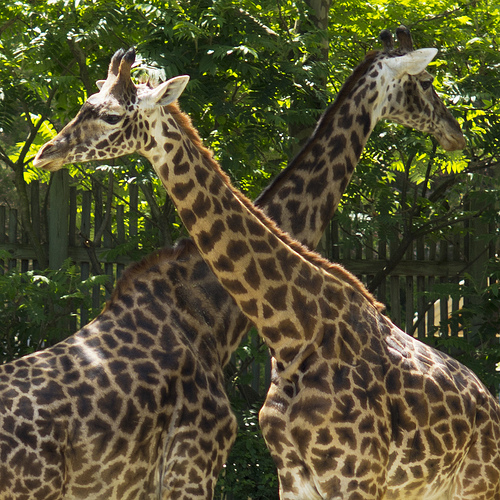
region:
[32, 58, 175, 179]
head of the photo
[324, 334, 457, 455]
brown spots on the animal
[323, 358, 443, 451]
white lines on the giraffe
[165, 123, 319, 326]
neck of the giraffe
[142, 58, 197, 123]
ear of the giraffe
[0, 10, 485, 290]
two different giraffes in the photo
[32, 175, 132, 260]
fence behind the giraffes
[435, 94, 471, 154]
nose of the giraffe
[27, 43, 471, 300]
giraffes facing different directions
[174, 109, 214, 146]
hair on the back of the giraffe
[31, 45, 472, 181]
Two giraffes in front of trees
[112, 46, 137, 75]
Protrusions on giraffe on the left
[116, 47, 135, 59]
Black hairs sticking out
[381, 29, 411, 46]
Giraffe on right with protrusions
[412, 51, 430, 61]
The back of the ear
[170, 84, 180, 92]
The front of the ear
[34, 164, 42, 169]
Upper lip sticking out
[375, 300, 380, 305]
Brown hairs on lower neck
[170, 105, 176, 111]
Hairs below the ear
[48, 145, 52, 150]
The nostril open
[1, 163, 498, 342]
A wooden fence.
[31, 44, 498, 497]
A giraffe turned to the left.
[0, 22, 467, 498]
A giraffe turned to the right.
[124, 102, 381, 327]
Two giraffe's necks that are crisscrossed.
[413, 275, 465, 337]
A view of an object through the fence slats.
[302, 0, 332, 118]
A tree branch.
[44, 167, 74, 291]
A wooden fence post.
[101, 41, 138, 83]
A giraffe's horns.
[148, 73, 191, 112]
A giraffe's ear.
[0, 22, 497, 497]
Two giraffes side by side.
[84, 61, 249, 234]
this is a giraffe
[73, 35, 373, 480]
the giraffes are two in number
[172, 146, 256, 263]
this is the neck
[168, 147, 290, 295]
the neck is long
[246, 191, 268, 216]
this is the fur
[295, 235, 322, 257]
the fur is brown in color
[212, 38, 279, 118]
this is a tree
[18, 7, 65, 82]
the leaves are green in color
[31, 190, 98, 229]
this is a fence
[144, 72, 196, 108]
this is the ear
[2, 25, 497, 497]
THE GIRAFFES HAVE DARK SPOTS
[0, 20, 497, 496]
TWO GIRAFFES ARE STANDING TOGETHER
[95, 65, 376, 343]
THE GIRAFFES HAVE LONG NECKS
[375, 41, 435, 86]
THE GIRAFFE HAS A WHITE EAR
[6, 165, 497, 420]
THE FENCE IS WOODEN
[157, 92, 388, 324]
THE GIRAFFE HAS A BLACK MANE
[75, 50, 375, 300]
THIS GIRAFFE HAS A BROWN MANE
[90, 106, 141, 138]
THIS IS A GIRAFFE'S EYE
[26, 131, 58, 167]
THIS IS A GIRAFFE'S NOSE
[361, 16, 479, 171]
THIS IS A GIRAFFE'S HEAD